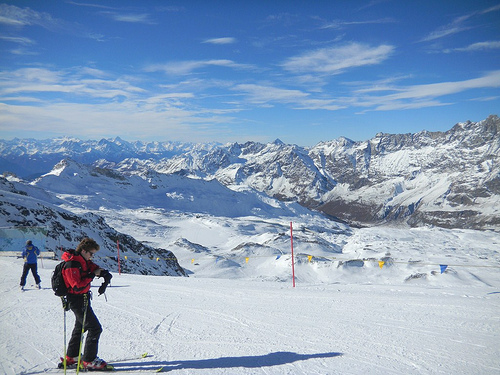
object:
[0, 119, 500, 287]
snow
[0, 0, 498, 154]
blue sky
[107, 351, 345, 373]
shadow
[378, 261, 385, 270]
flags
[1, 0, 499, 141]
sky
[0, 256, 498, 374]
snow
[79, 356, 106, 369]
shoes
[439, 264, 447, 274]
flag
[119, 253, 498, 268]
rope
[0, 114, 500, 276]
mountain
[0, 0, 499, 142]
cloud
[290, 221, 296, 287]
pole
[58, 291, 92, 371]
poles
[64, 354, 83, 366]
ski shoes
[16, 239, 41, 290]
person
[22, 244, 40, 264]
jacket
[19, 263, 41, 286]
pants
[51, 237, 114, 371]
skier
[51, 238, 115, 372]
man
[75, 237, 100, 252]
hair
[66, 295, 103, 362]
ski poles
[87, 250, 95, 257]
ski goggles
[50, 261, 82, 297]
backpack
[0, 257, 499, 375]
ground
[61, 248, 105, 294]
red jacket